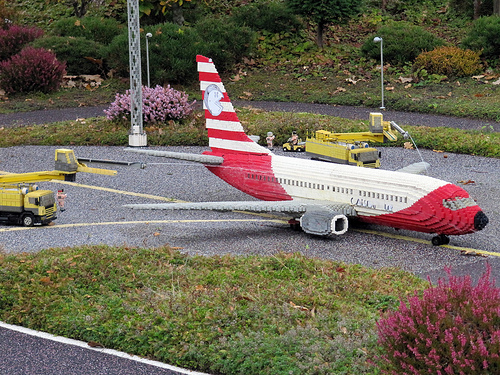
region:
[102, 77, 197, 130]
Pretty purple flowering bush.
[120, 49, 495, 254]
Red and white airplane sitting on pavement.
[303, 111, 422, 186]
Bright yellow truck beside airplane.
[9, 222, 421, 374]
Patch of grass in middle of concrete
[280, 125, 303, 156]
Small yellow jeep type vehicle with person driving.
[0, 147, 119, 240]
Yellow truck with lift type apparatus.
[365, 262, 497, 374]
Bush with violet colored flowers.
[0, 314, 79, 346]
White line painted on asphalt.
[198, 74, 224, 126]
Graphic design on tail of plane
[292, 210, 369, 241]
Plane engine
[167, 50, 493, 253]
plane is made from legos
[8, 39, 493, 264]
toys are on the ground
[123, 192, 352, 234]
wings are gray and long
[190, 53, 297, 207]
back of plane is red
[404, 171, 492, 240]
front of plane is red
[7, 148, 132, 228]
yellow truck near plane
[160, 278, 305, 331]
grass is very green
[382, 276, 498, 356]
grass has plants and flowers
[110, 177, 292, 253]
street has lines on it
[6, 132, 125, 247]
trucks are yellow and small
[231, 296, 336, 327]
part of some plants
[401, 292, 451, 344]
top of a pink plant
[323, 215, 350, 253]
part of an engine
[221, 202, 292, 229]
edge of a wing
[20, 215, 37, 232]
part of a front wheel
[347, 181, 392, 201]
part of some windows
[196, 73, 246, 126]
part of a tail wing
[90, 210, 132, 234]
part of a yellow line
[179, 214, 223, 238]
part of a runway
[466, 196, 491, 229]
tip of the plane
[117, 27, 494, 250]
red and white airplane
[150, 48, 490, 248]
airplane made of legos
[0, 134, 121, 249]
yellow truck on the concrete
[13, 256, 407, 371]
grass by the concrete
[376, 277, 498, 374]
bush with pink flowers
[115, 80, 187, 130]
big pink flowering bush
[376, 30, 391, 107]
light pole is silver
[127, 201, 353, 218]
airplane has gray wings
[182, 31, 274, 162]
airplane has red and white tail fin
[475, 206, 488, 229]
nose of plane is black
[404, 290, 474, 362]
fuchsia flowers growing on a shrub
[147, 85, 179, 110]
pink flowers on a shrub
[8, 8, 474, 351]
diorama of toy vehicles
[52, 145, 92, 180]
yellow crane on a truck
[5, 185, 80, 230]
yellow and gray construction truck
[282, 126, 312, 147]
person driving a yellow jeep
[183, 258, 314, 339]
thick green grass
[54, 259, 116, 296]
thick green shrubs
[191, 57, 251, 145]
red and white stripes on tail fin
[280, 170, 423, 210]
windows on the airplane